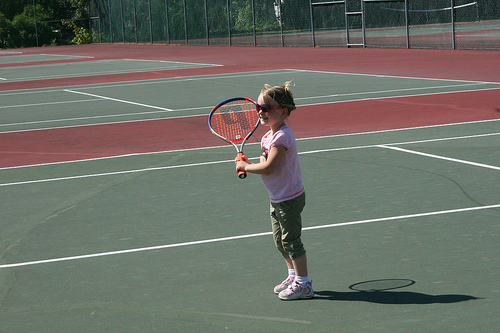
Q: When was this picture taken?
A: Daytime.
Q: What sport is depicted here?
A: Tennis.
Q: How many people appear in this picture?
A: One.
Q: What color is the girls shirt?
A: Pink.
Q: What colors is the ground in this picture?
A: Red and green.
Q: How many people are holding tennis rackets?
A: One.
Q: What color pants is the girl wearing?
A: Green.